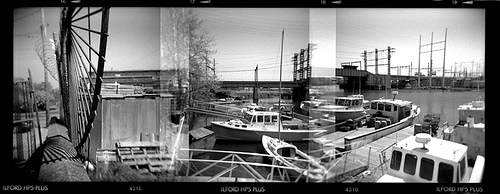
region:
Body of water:
[344, 85, 484, 135]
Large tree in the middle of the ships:
[158, 5, 222, 117]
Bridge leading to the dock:
[125, 145, 336, 180]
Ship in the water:
[211, 109, 330, 139]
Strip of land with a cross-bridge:
[86, 70, 484, 98]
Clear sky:
[13, 5, 485, 81]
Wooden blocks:
[115, 136, 178, 172]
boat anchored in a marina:
[211, 102, 326, 144]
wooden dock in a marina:
[321, 122, 433, 176]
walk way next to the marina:
[168, 147, 310, 179]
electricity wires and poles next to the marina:
[207, 28, 449, 88]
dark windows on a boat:
[386, 149, 457, 182]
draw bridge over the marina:
[171, 56, 368, 97]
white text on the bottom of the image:
[1, 182, 496, 192]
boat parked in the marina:
[442, 92, 491, 159]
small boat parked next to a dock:
[252, 126, 328, 179]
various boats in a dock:
[240, 72, 478, 180]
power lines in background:
[218, 46, 457, 74]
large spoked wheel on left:
[46, 10, 143, 160]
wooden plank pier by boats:
[307, 126, 435, 183]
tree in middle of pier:
[160, 17, 237, 111]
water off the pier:
[357, 75, 497, 140]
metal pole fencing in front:
[159, 138, 317, 186]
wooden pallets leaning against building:
[91, 128, 183, 183]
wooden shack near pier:
[91, 77, 181, 149]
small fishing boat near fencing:
[261, 124, 331, 179]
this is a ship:
[204, 90, 313, 136]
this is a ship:
[290, 85, 469, 149]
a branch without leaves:
[187, 40, 220, 60]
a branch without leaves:
[169, 50, 199, 90]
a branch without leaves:
[189, 42, 229, 94]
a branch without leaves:
[183, 11, 215, 54]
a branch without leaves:
[173, 28, 224, 79]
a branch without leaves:
[184, 55, 226, 92]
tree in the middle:
[157, 8, 222, 120]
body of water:
[66, 88, 488, 153]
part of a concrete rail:
[35, 115, 90, 176]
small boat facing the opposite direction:
[258, 132, 326, 178]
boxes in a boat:
[372, 118, 383, 124]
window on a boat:
[388, 148, 399, 168]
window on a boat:
[417, 153, 432, 178]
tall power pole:
[279, 28, 286, 97]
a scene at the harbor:
[6, 4, 498, 182]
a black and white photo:
[13, 12, 490, 192]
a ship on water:
[202, 100, 344, 159]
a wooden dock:
[265, 125, 460, 185]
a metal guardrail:
[162, 137, 398, 183]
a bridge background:
[183, 31, 498, 101]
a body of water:
[391, 75, 492, 124]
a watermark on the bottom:
[2, 173, 489, 193]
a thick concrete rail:
[28, 108, 105, 193]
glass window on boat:
[243, 113, 255, 120]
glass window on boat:
[252, 115, 256, 125]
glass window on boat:
[255, 114, 264, 122]